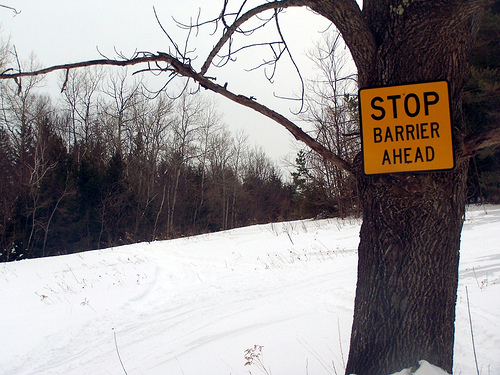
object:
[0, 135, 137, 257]
evergreens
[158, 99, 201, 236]
trees